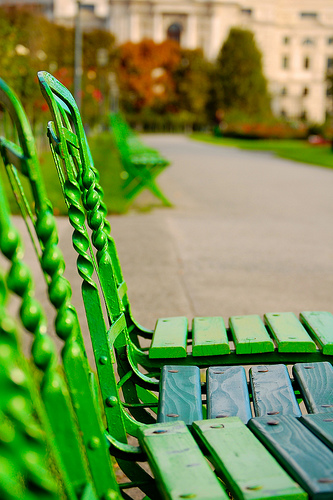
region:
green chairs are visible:
[15, 167, 328, 433]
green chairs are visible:
[52, 260, 312, 497]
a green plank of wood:
[145, 307, 188, 357]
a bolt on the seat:
[163, 404, 177, 417]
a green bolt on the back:
[102, 390, 122, 411]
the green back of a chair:
[36, 58, 150, 353]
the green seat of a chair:
[142, 303, 330, 353]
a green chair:
[101, 98, 176, 214]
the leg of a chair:
[131, 168, 173, 206]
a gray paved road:
[140, 124, 331, 212]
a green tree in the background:
[210, 24, 277, 130]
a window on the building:
[297, 50, 317, 71]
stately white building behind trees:
[55, 7, 324, 153]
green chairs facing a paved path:
[94, 92, 182, 206]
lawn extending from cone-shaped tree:
[186, 25, 324, 163]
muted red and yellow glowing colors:
[4, 34, 173, 104]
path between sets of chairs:
[4, 176, 312, 307]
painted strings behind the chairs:
[4, 122, 133, 356]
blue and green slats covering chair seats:
[143, 305, 323, 486]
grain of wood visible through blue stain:
[158, 365, 325, 409]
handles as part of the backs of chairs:
[34, 59, 97, 189]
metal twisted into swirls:
[59, 164, 123, 288]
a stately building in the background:
[111, 2, 329, 148]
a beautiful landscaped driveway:
[122, 115, 301, 297]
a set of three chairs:
[24, 245, 314, 488]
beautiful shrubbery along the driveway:
[9, 31, 126, 127]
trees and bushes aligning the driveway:
[126, 28, 286, 147]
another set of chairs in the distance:
[106, 114, 188, 216]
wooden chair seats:
[155, 364, 322, 437]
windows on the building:
[270, 30, 330, 127]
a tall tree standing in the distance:
[213, 26, 278, 135]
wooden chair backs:
[18, 380, 130, 473]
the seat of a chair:
[148, 307, 332, 361]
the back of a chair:
[35, 64, 154, 346]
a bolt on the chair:
[166, 407, 183, 421]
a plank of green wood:
[146, 311, 189, 362]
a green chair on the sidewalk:
[34, 67, 332, 405]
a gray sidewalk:
[131, 122, 331, 315]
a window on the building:
[275, 49, 292, 71]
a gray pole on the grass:
[72, 13, 87, 117]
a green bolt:
[103, 391, 119, 409]